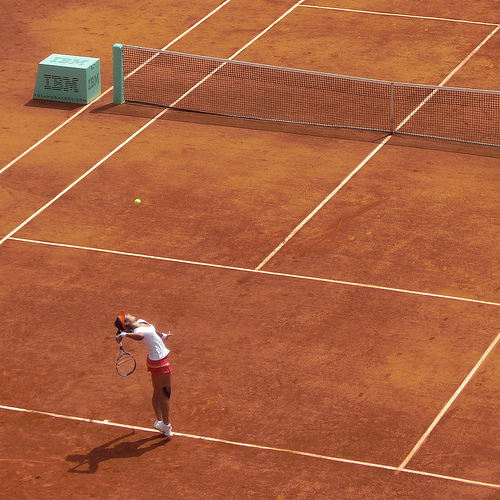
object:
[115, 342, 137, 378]
racket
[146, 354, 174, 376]
skirt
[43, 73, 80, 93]
logo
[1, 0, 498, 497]
court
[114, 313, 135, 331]
head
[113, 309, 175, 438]
lady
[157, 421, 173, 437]
shoes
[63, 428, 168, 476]
shadow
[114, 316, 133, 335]
hair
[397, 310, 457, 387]
prints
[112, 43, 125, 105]
net frame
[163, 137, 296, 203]
wall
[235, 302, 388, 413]
colour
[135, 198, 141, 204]
ball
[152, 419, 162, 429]
shoes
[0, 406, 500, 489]
lines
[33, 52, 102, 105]
box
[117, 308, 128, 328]
visor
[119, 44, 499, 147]
net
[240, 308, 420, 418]
floor